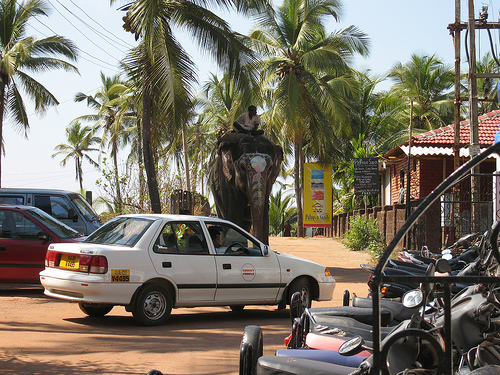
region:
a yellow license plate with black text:
[56, 255, 80, 269]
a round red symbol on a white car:
[238, 263, 257, 280]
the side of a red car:
[1, 203, 89, 293]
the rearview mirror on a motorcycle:
[403, 291, 421, 306]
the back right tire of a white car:
[133, 288, 170, 325]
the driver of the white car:
[207, 223, 248, 254]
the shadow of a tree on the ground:
[0, 349, 151, 374]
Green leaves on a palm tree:
[273, 67, 308, 108]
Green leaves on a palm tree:
[157, 59, 202, 145]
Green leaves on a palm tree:
[197, 10, 260, 77]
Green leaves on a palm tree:
[19, 55, 82, 92]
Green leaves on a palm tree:
[24, 32, 72, 54]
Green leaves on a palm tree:
[7, 84, 27, 131]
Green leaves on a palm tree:
[13, 1, 52, 43]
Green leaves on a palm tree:
[360, 91, 385, 137]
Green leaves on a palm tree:
[375, 49, 440, 129]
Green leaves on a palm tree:
[343, 131, 374, 153]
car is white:
[38, 207, 338, 330]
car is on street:
[28, 206, 341, 326]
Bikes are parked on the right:
[236, 220, 498, 372]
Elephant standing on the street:
[208, 128, 289, 298]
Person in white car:
[204, 225, 239, 254]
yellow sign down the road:
[303, 156, 335, 234]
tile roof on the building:
[408, 96, 498, 156]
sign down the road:
[350, 150, 382, 207]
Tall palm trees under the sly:
[122, 5, 477, 198]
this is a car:
[34, 171, 351, 347]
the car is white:
[35, 175, 362, 357]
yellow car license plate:
[48, 233, 116, 285]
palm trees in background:
[16, 9, 479, 243]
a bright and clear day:
[3, 5, 490, 356]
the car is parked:
[20, 134, 357, 364]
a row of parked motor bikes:
[228, 183, 485, 373]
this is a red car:
[3, 189, 98, 327]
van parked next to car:
[5, 166, 123, 264]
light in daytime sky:
[1, 1, 497, 194]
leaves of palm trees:
[220, 2, 367, 156]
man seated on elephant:
[208, 104, 283, 241]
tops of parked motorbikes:
[260, 229, 497, 373]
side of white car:
[42, 211, 336, 325]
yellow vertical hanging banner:
[301, 161, 333, 228]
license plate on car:
[55, 251, 82, 270]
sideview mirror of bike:
[339, 336, 364, 355]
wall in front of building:
[322, 157, 426, 250]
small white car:
[39, 209, 335, 325]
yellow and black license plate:
[55, 252, 81, 271]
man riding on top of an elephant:
[204, 104, 283, 249]